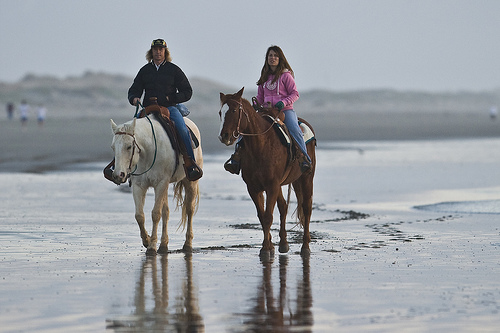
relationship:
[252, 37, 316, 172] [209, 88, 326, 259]
girl riding horse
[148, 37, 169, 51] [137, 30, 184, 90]
ballcap on man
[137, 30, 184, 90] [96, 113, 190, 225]
man on horse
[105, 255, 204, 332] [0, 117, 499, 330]
reflection on beach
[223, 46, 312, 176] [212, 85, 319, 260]
girl on horse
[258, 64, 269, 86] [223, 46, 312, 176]
hair on girl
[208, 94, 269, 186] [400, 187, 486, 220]
horse walking through water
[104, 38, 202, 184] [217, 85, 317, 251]
man riding horse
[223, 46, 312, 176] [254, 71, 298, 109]
girl wears pink top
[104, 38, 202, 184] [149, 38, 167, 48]
man wears ballcap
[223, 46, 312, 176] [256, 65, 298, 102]
girl wearing jacket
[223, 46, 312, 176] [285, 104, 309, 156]
girl wearing blue pants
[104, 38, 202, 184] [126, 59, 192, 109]
man wearing black jacket